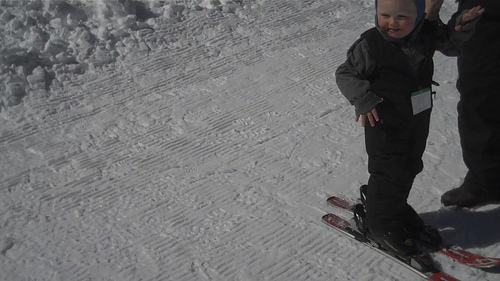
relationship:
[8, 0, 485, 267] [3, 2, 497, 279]
snow on ground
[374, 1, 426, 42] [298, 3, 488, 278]
head belonging to baby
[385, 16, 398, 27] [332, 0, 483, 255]
nose belonging to baby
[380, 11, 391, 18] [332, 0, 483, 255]
eye belonging to baby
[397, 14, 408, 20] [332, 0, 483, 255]
eye belonging to baby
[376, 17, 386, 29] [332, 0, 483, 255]
babycheek belonging to baby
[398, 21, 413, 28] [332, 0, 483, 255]
babycheek belonging to baby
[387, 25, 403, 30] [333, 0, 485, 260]
lip belonging to child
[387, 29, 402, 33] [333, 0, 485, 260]
lip belonging to child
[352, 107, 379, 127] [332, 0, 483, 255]
hand belonging to baby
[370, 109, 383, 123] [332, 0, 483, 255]
finger belonging to baby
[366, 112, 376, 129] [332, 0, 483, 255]
finger belonging to baby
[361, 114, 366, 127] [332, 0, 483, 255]
finger belonging to baby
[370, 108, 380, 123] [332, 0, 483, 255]
finger belonging to baby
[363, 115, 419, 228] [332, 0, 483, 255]
leg belonging to baby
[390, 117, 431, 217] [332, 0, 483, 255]
leg belonging to baby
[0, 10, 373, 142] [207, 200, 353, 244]
ski track edged in snow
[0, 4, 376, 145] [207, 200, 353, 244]
ski track edged in snow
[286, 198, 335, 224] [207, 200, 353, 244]
ski track edged in snow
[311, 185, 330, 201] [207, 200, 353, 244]
ski track edged in snow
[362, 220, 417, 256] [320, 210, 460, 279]
foot strapped to ski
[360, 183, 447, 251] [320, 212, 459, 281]
foot strapped to ski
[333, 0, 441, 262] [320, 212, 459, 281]
child standing on ski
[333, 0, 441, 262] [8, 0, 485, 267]
child standing on snow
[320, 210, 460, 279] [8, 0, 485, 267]
ski sitting on snow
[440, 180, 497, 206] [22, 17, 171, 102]
shoe standing in snow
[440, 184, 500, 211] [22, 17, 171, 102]
shoe standing in snow